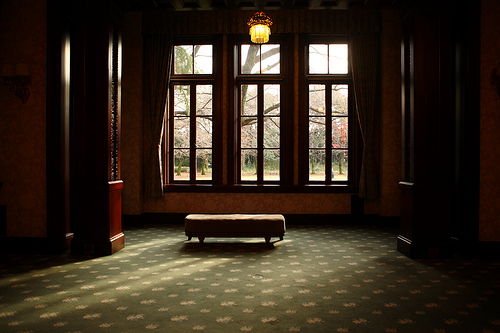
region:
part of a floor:
[273, 279, 310, 319]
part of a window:
[253, 154, 261, 166]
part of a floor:
[304, 282, 330, 311]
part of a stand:
[273, 99, 311, 162]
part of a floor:
[305, 259, 338, 305]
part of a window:
[262, 117, 275, 142]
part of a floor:
[320, 273, 355, 307]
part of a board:
[89, 167, 137, 225]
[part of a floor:
[327, 258, 360, 318]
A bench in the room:
[181, 206, 289, 246]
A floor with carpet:
[280, 248, 352, 305]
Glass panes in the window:
[307, 84, 347, 172]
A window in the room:
[164, 44, 351, 184]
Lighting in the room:
[240, 9, 277, 47]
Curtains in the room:
[147, 44, 169, 197]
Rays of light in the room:
[124, 245, 191, 296]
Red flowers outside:
[327, 119, 349, 151]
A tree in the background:
[165, 43, 198, 89]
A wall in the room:
[120, 92, 145, 207]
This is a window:
[301, 74, 351, 194]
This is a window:
[236, 76, 286, 191]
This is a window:
[169, 78, 219, 193]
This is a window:
[173, 45, 218, 79]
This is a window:
[239, 33, 287, 82]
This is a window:
[306, 39, 358, 83]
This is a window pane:
[307, 76, 329, 116]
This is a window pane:
[309, 113, 332, 150]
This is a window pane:
[330, 113, 346, 150]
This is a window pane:
[306, 145, 326, 184]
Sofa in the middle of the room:
[185, 212, 289, 242]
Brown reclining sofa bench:
[182, 212, 292, 247]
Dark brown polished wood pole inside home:
[45, 5, 130, 255]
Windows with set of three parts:
[164, 37, 354, 187]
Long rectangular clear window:
[171, 43, 215, 183]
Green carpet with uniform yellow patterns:
[3, 220, 495, 330]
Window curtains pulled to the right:
[347, 30, 381, 200]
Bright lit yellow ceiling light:
[248, 11, 273, 43]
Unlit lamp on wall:
[1, 57, 34, 104]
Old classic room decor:
[37, 2, 480, 257]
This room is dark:
[72, 15, 467, 294]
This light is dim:
[167, 11, 315, 68]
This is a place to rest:
[164, 186, 353, 285]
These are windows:
[159, 64, 354, 216]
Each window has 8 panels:
[153, 36, 252, 215]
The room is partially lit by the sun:
[145, 49, 428, 323]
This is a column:
[36, 26, 187, 244]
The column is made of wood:
[62, 27, 167, 252]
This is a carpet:
[31, 269, 348, 331]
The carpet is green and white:
[111, 244, 348, 332]